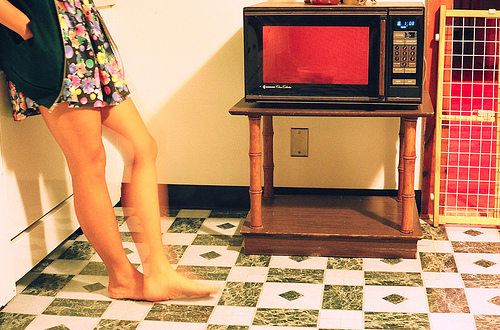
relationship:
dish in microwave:
[289, 58, 343, 89] [237, 4, 425, 109]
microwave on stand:
[222, 4, 430, 116] [227, 95, 438, 260]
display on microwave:
[393, 17, 421, 32] [240, 1, 431, 113]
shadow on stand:
[14, 146, 84, 258] [227, 95, 438, 260]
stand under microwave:
[227, 95, 433, 260] [240, 1, 431, 113]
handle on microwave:
[377, 17, 389, 103] [240, 1, 431, 113]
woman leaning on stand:
[5, 1, 223, 308] [227, 95, 438, 260]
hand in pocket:
[20, 11, 52, 61] [10, 11, 63, 103]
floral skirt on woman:
[11, 6, 126, 122] [5, 1, 223, 308]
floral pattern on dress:
[16, 10, 136, 118] [2, 0, 132, 121]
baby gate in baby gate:
[430, 6, 499, 233] [430, 2, 500, 228]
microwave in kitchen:
[240, 0, 430, 109] [31, 3, 492, 328]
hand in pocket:
[25, 18, 55, 54] [14, 22, 49, 99]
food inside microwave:
[296, 62, 336, 81] [240, 1, 431, 113]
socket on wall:
[287, 125, 311, 160] [107, 3, 427, 197]